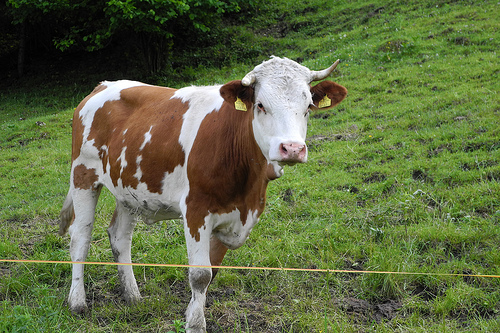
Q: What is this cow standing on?
A: Grass.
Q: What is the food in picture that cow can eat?
A: Grass.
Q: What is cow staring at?
A: Camera.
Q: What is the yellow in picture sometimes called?
A: Barrier.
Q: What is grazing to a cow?
A: To eat.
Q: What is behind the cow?
A: Green trees.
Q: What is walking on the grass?
A: A cow.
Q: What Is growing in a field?
A: Green grass.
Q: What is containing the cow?
A: A cord.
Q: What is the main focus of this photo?
A: A cow.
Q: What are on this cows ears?
A: Tags.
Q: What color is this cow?
A: Brown and white.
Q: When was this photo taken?
A: Outside, during the daytime.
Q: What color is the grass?
A: Green.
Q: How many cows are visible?
A: One.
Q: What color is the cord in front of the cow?
A: Yellow.